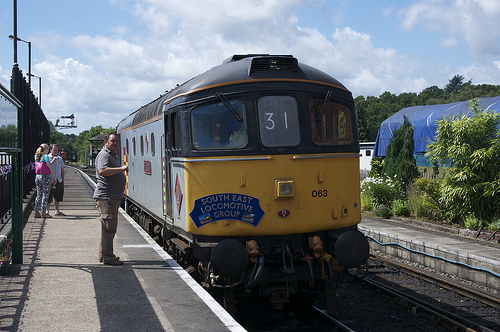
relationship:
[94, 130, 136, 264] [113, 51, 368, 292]
man beside train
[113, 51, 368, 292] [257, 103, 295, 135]
train has number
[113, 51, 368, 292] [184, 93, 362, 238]
train has front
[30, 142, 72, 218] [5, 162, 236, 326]
people on sidewalk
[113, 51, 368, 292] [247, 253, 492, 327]
train on tracks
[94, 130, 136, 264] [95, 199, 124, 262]
man wearing pants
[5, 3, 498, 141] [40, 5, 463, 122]
sky has clouds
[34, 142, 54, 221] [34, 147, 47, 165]
woman with ponytail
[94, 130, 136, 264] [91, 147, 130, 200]
man wearing shirt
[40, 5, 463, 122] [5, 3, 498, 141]
clouds in sky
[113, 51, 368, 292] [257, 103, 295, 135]
train with number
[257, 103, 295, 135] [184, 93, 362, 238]
number on front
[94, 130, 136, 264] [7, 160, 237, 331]
man on platform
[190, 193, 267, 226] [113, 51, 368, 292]
placard on train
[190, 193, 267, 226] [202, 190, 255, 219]
placard says south east locomotiv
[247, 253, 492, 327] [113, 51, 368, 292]
tracks for train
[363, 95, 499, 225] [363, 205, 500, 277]
foilage near platform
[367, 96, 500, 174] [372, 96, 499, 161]
structure covered in tarp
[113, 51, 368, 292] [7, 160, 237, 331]
train stops at platform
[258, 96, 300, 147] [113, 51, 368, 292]
window in train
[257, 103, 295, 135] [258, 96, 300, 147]
number on window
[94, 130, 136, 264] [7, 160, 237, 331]
male on platform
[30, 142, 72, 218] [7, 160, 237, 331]
people waiting on platform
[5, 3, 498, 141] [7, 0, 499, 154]
sky in distance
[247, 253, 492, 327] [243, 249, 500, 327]
tracks on ground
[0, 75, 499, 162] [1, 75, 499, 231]
foilage on trees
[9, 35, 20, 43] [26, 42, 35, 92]
light on pole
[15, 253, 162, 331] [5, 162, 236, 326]
shadow on ground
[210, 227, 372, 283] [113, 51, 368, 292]
bumper on train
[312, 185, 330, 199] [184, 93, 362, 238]
number on front